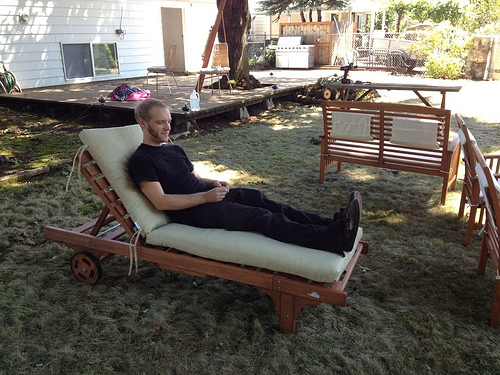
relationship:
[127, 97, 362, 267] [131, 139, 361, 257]
man wearing clothing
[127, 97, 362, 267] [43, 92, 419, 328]
man laying on chair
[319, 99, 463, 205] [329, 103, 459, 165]
bench with cushions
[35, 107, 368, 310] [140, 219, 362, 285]
lounge has cushion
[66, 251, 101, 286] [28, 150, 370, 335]
wheel of chair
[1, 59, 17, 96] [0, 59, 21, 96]
hose on hose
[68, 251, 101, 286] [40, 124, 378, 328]
wheel on chair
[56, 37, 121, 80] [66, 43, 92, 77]
screen on window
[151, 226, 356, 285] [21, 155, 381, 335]
cushion on chair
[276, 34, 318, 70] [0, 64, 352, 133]
grill on deck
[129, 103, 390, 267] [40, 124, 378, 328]
man laying on a chair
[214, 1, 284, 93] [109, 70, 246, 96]
tree trunk coming through a deck